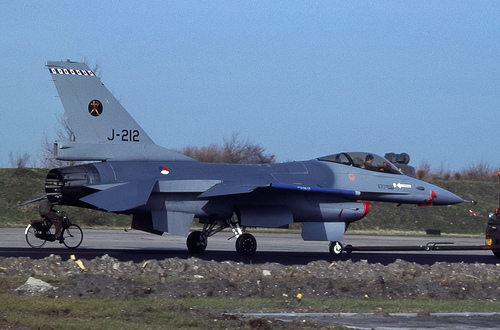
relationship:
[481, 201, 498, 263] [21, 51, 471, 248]
car with jet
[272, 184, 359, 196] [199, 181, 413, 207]
edge of jets wing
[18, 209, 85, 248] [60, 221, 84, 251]
bicycle has front tire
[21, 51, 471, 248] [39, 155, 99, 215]
jet has engine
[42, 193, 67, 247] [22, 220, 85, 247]
person on bicycle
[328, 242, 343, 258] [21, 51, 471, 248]
wheel on jet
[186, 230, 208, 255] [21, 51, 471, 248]
wheel on jet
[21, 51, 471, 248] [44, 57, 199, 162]
jet has tail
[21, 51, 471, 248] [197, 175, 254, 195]
jet has wing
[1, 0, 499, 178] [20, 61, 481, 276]
sky above jet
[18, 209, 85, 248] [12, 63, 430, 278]
bicycle near jet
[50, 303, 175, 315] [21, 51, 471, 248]
grass next to jet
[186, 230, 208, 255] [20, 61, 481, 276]
wheel on jet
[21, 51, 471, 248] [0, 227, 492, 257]
jet on road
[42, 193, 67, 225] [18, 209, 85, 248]
person riding bicycle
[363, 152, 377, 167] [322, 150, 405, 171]
pilot in cockpit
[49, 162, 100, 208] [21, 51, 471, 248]
engine on jet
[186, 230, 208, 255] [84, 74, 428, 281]
wheel are on jet